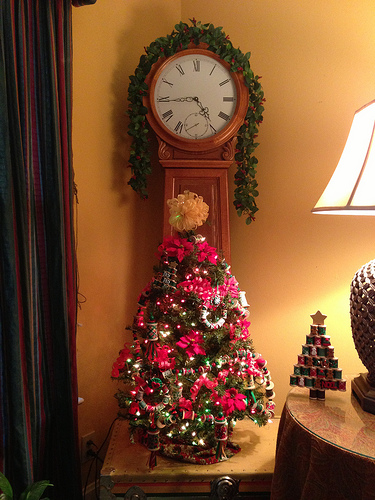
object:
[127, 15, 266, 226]
garland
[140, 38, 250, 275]
clock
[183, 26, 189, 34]
red flower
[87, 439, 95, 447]
outlet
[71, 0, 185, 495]
wall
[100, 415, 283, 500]
trunk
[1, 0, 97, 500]
curtains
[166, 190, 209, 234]
bow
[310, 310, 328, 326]
star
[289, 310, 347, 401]
tree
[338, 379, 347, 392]
spools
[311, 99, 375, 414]
lamp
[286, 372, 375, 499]
table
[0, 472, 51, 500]
leaves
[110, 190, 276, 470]
christmas tree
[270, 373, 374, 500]
table cloth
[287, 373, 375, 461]
glass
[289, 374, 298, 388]
spools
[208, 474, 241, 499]
latch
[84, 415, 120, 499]
cord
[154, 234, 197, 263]
poinsettia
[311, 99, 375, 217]
shade